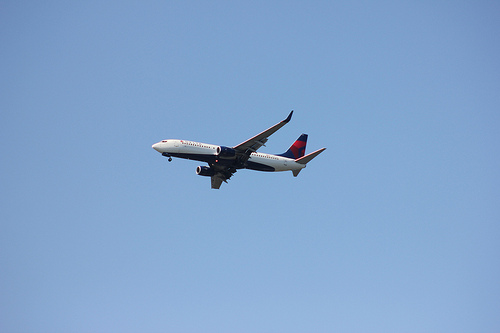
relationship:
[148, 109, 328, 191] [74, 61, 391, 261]
plane in mid air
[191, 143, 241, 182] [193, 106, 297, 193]
engines under wings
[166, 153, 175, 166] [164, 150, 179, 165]
wheel of landing gear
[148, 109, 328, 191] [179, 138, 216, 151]
plane has windows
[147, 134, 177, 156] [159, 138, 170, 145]
cockpit has windshield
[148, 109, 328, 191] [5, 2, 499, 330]
plane in air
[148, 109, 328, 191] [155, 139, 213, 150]
plane has people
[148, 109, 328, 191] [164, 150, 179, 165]
plane landing gear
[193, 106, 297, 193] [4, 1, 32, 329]
wings on left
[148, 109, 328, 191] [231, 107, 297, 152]
plane on right wing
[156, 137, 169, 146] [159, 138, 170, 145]
window of pilot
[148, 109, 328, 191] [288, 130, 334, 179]
plane has tail fins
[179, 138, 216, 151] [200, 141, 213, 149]
windows of people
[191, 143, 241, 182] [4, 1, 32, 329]
engines on left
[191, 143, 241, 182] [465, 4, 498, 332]
engines on right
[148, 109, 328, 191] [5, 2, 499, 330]
plane flying in air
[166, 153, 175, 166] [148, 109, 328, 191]
wheel on plane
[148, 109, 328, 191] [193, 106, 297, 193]
plane has wings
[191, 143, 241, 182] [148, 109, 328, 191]
engines on plane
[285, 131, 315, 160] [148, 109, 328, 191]
tail on plane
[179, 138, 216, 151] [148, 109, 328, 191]
windows on plane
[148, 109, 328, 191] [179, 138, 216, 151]
plane for passengers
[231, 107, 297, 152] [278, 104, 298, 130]
wing has tip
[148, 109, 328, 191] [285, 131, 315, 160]
plane has tail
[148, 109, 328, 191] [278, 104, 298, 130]
plane has tip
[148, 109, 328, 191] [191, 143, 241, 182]
plane has engines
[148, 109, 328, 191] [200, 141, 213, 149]
plane of people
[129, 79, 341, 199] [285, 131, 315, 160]
plane has tail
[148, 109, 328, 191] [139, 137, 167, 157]
plane has nose